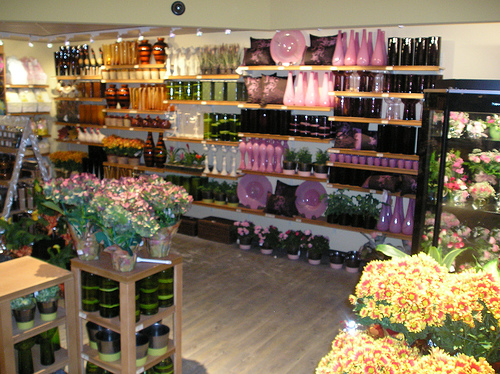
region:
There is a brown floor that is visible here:
[226, 288, 273, 363]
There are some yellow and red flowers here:
[399, 273, 428, 311]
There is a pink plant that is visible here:
[106, 187, 144, 267]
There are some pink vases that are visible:
[343, 25, 382, 62]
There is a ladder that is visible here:
[10, 126, 53, 194]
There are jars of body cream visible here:
[96, 283, 119, 328]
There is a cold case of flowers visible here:
[460, 120, 499, 203]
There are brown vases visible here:
[125, 37, 170, 78]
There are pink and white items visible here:
[12, 42, 47, 101]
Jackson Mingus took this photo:
[64, 60, 434, 372]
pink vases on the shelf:
[333, 24, 389, 64]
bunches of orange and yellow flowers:
[308, 249, 499, 372]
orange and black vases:
[138, 35, 165, 65]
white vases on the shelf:
[198, 141, 240, 175]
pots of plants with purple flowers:
[46, 158, 187, 270]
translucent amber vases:
[124, 80, 165, 114]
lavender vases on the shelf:
[369, 193, 411, 234]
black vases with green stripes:
[78, 272, 178, 322]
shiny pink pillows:
[238, 66, 281, 109]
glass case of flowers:
[410, 79, 499, 269]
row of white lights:
[2, 28, 233, 49]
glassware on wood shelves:
[54, 32, 436, 234]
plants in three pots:
[53, 172, 185, 268]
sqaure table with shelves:
[76, 247, 183, 372]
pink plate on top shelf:
[270, 31, 306, 64]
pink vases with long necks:
[332, 28, 384, 67]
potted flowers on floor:
[232, 221, 322, 263]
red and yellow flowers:
[318, 255, 497, 372]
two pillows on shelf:
[242, 73, 294, 108]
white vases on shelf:
[200, 156, 237, 178]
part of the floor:
[303, 293, 315, 321]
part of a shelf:
[127, 254, 144, 281]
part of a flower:
[398, 313, 413, 369]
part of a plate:
[312, 178, 319, 194]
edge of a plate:
[304, 104, 313, 117]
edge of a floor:
[239, 310, 265, 337]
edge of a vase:
[355, 138, 367, 162]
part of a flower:
[416, 285, 431, 308]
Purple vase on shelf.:
[388, 202, 407, 241]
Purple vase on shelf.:
[401, 200, 413, 239]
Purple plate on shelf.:
[299, 181, 326, 229]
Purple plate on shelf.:
[234, 174, 278, 205]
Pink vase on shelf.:
[270, 143, 282, 179]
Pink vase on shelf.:
[248, 135, 263, 170]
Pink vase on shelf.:
[234, 136, 249, 174]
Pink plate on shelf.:
[272, 35, 315, 74]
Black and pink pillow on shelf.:
[308, 40, 340, 75]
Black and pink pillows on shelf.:
[251, 38, 273, 79]